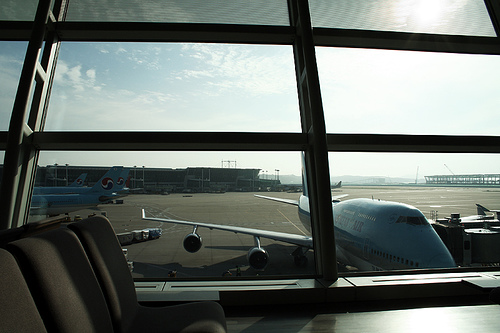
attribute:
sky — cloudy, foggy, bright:
[1, 1, 500, 183]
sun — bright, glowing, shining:
[403, 2, 473, 33]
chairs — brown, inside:
[64, 206, 226, 332]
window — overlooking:
[309, 0, 499, 48]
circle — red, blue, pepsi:
[99, 175, 116, 191]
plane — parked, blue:
[137, 143, 496, 273]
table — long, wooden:
[131, 266, 500, 308]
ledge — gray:
[38, 124, 500, 159]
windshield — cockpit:
[397, 212, 431, 225]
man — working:
[234, 262, 245, 277]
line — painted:
[275, 210, 316, 252]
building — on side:
[1, 159, 284, 199]